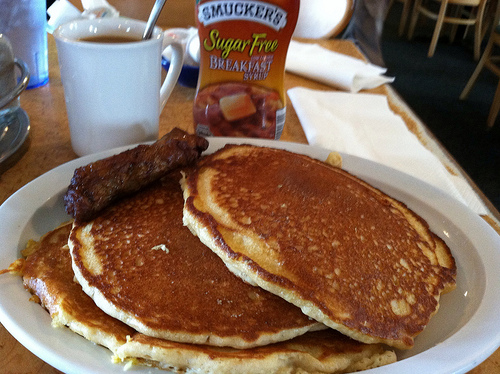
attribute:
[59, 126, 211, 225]
piece — sausage, crispy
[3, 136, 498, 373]
plate — round, white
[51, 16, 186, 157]
cup — white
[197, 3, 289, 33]
name — smuckers, brand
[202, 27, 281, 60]
letters — yellow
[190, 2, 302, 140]
bottle — plastic, orange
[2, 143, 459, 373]
pancakes — few, crispy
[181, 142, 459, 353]
pancake — big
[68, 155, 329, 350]
pancake — big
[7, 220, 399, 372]
pancake — big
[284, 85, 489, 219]
handkerchief — white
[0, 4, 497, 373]
table — brown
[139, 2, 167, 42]
spoon — silver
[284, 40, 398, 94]
napkin — white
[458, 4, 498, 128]
chair — wood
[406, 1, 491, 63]
chair — wood